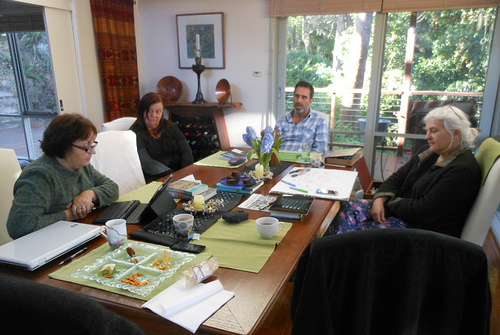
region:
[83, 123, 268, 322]
the table is wooden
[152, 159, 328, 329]
the table is wooden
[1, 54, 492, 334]
people sitting around table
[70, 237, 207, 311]
bowl of snacks on place mat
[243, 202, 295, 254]
white cup of coffee on table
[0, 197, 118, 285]
white lap top on table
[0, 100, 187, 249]
lady looking at tablet on table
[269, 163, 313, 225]
tablet on table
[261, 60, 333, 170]
man wearing plaid shirt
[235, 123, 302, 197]
plant on table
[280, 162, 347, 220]
pens on sheet of paper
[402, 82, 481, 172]
lady with grey hair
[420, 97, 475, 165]
a woman with grey hair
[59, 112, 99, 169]
a woman wearing glasses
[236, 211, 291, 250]
a white coffee cup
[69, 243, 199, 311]
a tray of snacks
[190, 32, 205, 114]
a tall candle holder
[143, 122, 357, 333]
a long wooden table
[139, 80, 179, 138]
a woman with red hair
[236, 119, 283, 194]
a plant on a table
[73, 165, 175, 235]
a black laptop computer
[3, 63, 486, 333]
four people sitting around a table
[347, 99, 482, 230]
Woman sitting in a chair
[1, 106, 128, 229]
Woman with glasses in meeting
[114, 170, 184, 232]
Black laptop on table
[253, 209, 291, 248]
White coffee cup on placemat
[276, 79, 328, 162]
Man with beard sitting at table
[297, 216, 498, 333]
Black jacket behind chair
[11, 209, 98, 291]
White laptop placed on table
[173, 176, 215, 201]
Two books sitting on table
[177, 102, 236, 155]
Wine rack in dining room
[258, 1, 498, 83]
Sliding doors in dining room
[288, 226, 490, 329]
black coat draped over chair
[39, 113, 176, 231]
Woman looks at notebook on table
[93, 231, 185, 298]
plate divided into four square sections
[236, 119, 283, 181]
blue flowers on the table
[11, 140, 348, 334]
brown wooden rectangular table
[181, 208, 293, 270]
yellow green place mat on table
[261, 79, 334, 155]
man wearing blue plaid shirt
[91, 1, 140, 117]
red and orange tapestry on wall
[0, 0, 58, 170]
glass sliding door in background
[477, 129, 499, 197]
green cloth draped over white chair